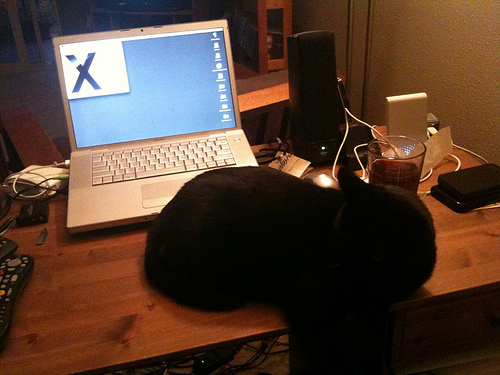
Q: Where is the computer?
A: On the table.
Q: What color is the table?
A: Brown.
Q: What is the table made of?
A: Wood.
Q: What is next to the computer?
A: The cat.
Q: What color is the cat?
A: Black.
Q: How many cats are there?
A: One.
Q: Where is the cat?
A: Next to the computer.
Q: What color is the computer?
A: Silver.